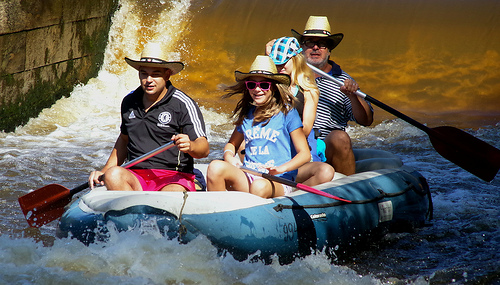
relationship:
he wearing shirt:
[86, 42, 209, 192] [112, 84, 208, 169]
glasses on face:
[245, 81, 273, 91] [244, 81, 269, 104]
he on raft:
[86, 42, 209, 192] [76, 169, 434, 244]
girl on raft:
[263, 35, 335, 193] [76, 169, 434, 244]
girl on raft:
[206, 55, 311, 199] [76, 169, 434, 244]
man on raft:
[291, 15, 374, 176] [76, 169, 434, 244]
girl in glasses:
[200, 50, 310, 198] [240, 76, 272, 91]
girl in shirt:
[200, 50, 310, 198] [233, 99, 303, 186]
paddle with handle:
[15, 127, 197, 235] [61, 136, 182, 195]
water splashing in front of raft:
[1, 211, 361, 280] [63, 181, 450, 245]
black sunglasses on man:
[301, 40, 329, 50] [295, 17, 368, 178]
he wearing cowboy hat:
[86, 39, 213, 189] [123, 42, 184, 76]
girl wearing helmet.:
[263, 35, 335, 193] [263, 17, 293, 73]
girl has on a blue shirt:
[206, 55, 311, 199] [226, 102, 322, 182]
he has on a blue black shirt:
[86, 39, 213, 189] [113, 82, 205, 174]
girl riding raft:
[206, 55, 311, 199] [52, 146, 433, 261]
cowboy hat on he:
[123, 42, 184, 76] [86, 42, 209, 192]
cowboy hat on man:
[290, 16, 343, 51] [291, 15, 374, 176]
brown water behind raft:
[8, 1, 498, 130] [52, 146, 433, 261]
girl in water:
[206, 55, 311, 199] [8, 102, 498, 283]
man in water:
[291, 15, 374, 176] [8, 102, 498, 283]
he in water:
[86, 42, 209, 192] [8, 102, 498, 283]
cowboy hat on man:
[294, 10, 344, 48] [291, 15, 374, 176]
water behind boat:
[352, 47, 474, 84] [55, 148, 435, 266]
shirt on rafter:
[234, 102, 304, 182] [23, 25, 478, 270]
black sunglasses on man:
[301, 37, 333, 49] [304, 15, 374, 172]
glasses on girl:
[245, 81, 273, 91] [200, 50, 310, 198]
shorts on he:
[122, 168, 200, 208] [86, 42, 209, 192]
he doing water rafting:
[86, 42, 209, 192] [0, 177, 481, 282]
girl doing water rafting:
[206, 55, 311, 199] [0, 177, 481, 282]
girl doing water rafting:
[263, 35, 335, 193] [0, 177, 481, 282]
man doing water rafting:
[291, 15, 374, 176] [0, 177, 481, 282]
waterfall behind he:
[6, 2, 498, 132] [86, 42, 209, 192]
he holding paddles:
[86, 42, 209, 192] [6, 117, 379, 264]